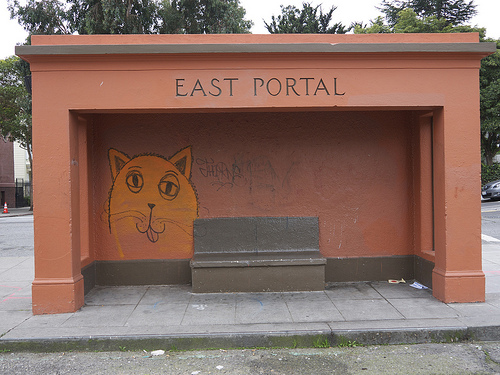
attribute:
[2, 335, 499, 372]
road — cement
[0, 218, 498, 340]
pavement — brown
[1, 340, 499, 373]
road — cement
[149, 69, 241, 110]
letters — gray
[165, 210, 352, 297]
bench — brown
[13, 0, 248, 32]
tree — green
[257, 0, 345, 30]
tree — green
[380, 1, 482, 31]
tree — green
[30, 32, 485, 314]
stage shade — orange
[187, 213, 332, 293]
bench — concrete, brown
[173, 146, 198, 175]
cone — white and orange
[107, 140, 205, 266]
cat — orange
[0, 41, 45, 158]
branch — green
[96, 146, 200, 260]
cat — yellow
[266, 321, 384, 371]
grass — green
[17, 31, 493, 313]
building — painted